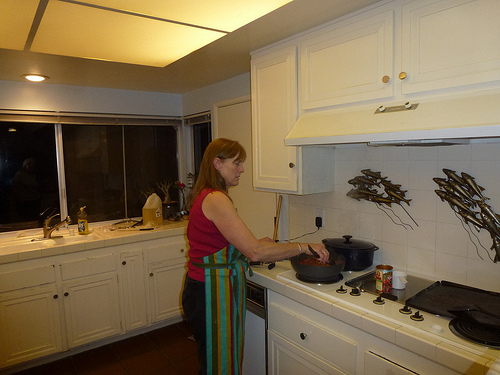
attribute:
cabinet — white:
[1, 233, 189, 372]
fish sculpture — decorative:
[432, 167, 500, 264]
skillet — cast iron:
[286, 249, 345, 280]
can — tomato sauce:
[374, 262, 394, 296]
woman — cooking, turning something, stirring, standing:
[180, 136, 332, 374]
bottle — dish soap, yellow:
[75, 203, 90, 235]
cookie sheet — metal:
[403, 279, 499, 324]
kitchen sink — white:
[18, 229, 107, 248]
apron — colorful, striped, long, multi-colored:
[202, 239, 248, 374]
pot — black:
[319, 233, 380, 273]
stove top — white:
[277, 260, 498, 357]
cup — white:
[392, 267, 410, 291]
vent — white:
[367, 138, 471, 148]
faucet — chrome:
[43, 211, 72, 242]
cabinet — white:
[248, 0, 499, 197]